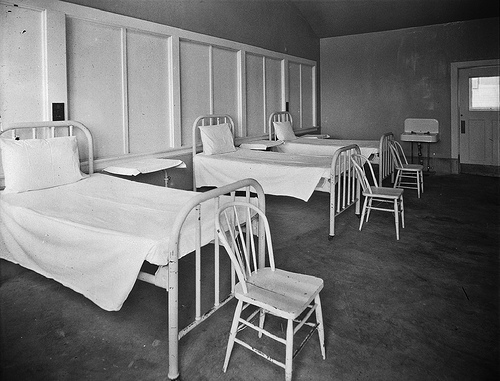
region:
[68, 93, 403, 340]
black and white photo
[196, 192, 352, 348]
chair in front of bed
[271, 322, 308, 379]
leg of the chair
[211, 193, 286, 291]
back of the chair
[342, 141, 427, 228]
two chairs next to each other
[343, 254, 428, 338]
ground next to chairs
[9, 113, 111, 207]
pillow on the bed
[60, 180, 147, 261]
sheet on the bed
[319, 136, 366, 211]
bars on the bed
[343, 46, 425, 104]
wall next to beds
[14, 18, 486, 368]
Photo taken during the day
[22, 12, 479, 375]
Nobody in the photo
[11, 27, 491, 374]
Photo taken in an infirmary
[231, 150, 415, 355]
Chairs at the end of the beds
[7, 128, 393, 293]
Beds with white blankets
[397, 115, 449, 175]
Sink on the far wall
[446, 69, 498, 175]
The door is closed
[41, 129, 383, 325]
The bed frames are metal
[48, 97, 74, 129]
Electrical outlet on the wall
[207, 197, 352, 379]
White chair on floor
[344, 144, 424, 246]
White chair on floor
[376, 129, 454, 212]
White chair on floor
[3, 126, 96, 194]
White pillow on bed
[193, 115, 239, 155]
White pillow on bed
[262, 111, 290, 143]
White pillow on bed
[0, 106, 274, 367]
White metal framed bed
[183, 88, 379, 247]
White metal framed bed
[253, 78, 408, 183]
White metal framed bed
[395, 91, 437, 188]
White sink on wall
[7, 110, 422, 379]
three sets of beds with chairs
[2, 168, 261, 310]
very standard bed with small matress and one sheet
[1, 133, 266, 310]
linnens are white for easy bleaching and sterilization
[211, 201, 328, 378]
older white wooden chair is in front of each bed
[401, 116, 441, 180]
older sink attached to wall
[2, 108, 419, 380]
hospital beds set up quickly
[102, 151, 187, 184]
a table lined with white cloth is beside each bed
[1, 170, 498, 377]
cement floor for easy clean up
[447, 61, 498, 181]
older white door to hospital bed area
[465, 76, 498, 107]
clear window in door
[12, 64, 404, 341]
Three hospital beds are in the room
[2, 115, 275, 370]
The bed has a metal frame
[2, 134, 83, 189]
The pillow is a white color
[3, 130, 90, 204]
The bed has one pillow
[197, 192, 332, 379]
A wooden chair is next to the bed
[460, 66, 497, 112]
The door has a window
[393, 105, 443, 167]
A sink is along the wall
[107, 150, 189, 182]
A table is next to the bed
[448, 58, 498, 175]
A door is along the wall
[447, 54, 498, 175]
The door is a white color